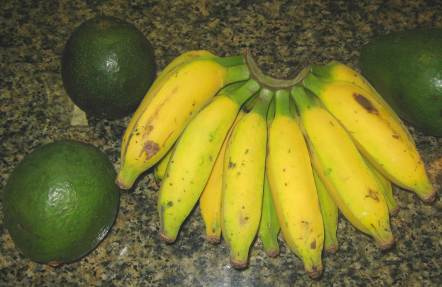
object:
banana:
[158, 77, 251, 241]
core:
[244, 59, 310, 90]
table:
[16, 10, 439, 262]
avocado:
[58, 13, 158, 118]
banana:
[267, 90, 325, 267]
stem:
[251, 87, 271, 116]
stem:
[231, 80, 259, 103]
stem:
[304, 75, 327, 94]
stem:
[274, 89, 293, 116]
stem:
[223, 65, 252, 83]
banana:
[220, 87, 271, 269]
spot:
[139, 138, 162, 161]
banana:
[312, 64, 438, 204]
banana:
[304, 90, 402, 254]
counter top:
[3, 1, 61, 132]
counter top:
[118, 217, 163, 284]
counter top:
[399, 207, 440, 285]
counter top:
[162, 7, 442, 36]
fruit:
[5, 135, 122, 265]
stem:
[289, 87, 313, 109]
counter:
[5, 3, 434, 284]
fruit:
[363, 36, 442, 133]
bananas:
[108, 42, 256, 190]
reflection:
[183, 251, 231, 287]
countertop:
[102, 251, 215, 276]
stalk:
[218, 53, 243, 66]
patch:
[348, 89, 383, 119]